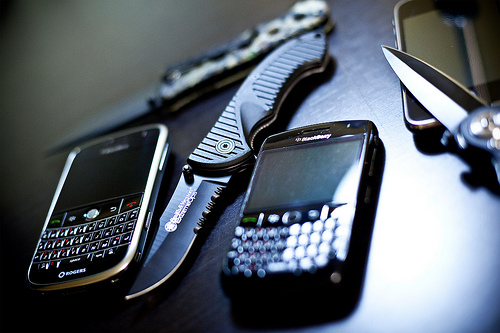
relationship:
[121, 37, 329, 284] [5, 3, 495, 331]
blade on table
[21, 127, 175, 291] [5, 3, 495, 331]
cellphone on table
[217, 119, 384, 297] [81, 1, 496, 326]
cellphone on desk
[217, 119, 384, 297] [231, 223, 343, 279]
cellphone has buttons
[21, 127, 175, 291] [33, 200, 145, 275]
cellphone has buttons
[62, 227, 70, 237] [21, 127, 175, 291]
button on a cellphone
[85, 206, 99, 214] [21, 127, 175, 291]
button on cellphone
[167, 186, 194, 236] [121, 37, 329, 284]
words on blade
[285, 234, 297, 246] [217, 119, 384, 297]
white button on cellphone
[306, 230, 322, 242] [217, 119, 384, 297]
white button on cellphone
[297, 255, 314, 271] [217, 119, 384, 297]
white button on cellphone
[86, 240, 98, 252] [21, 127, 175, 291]
white button on cellphone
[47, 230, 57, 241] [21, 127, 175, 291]
white button on cellphone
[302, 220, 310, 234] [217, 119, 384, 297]
button on cellphone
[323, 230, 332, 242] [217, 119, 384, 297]
button on cellphone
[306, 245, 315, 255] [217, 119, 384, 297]
button on cellphone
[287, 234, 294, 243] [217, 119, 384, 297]
button on cellphone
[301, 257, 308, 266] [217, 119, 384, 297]
button on cellphone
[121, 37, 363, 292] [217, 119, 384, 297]
blade between cellphone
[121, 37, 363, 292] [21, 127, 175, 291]
blade between cellphone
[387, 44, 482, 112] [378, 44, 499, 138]
blade of blade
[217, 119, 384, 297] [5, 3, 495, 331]
cellphone on table